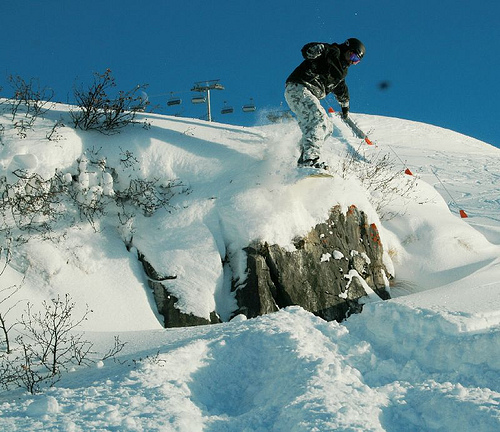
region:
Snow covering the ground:
[168, 266, 260, 303]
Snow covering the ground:
[212, 194, 314, 272]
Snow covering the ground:
[293, 177, 395, 260]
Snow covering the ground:
[287, 356, 376, 421]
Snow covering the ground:
[42, 292, 169, 392]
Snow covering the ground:
[207, 139, 275, 189]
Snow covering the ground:
[388, 102, 463, 180]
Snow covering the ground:
[101, 82, 190, 151]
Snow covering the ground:
[432, 227, 487, 319]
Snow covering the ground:
[328, 277, 418, 345]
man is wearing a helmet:
[323, 30, 389, 89]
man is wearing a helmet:
[337, 29, 365, 68]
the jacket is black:
[277, 35, 367, 125]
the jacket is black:
[289, 32, 391, 212]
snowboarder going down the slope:
[279, 31, 366, 171]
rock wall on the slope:
[247, 218, 385, 308]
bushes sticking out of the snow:
[21, 291, 121, 391]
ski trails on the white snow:
[403, 125, 485, 181]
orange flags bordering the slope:
[400, 162, 481, 234]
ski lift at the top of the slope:
[150, 77, 258, 130]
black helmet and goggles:
[339, 32, 365, 67]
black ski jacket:
[291, 35, 361, 102]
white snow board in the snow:
[287, 159, 334, 185]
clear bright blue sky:
[134, 19, 247, 66]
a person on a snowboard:
[275, 25, 382, 195]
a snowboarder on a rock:
[250, 10, 391, 202]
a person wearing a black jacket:
[290, 18, 390, 109]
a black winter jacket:
[284, 26, 375, 106]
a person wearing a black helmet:
[341, 30, 368, 65]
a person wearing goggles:
[340, 33, 370, 65]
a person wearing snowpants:
[275, 65, 339, 176]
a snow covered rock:
[150, 173, 435, 345]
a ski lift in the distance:
[152, 53, 280, 127]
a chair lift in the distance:
[151, 52, 283, 123]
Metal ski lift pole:
[187, 77, 224, 125]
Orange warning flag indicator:
[431, 164, 468, 224]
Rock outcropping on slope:
[118, 164, 404, 335]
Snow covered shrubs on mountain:
[4, 60, 183, 402]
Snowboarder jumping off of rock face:
[287, 53, 369, 183]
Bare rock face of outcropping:
[241, 203, 398, 333]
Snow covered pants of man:
[275, 83, 336, 163]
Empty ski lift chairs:
[218, 95, 278, 120]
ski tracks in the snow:
[418, 148, 498, 217]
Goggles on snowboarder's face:
[336, 48, 366, 63]